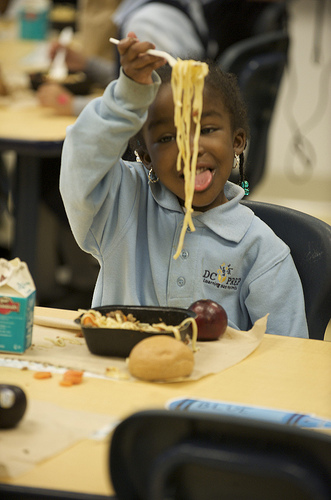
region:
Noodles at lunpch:
[153, 44, 232, 228]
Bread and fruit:
[101, 278, 238, 372]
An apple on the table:
[180, 288, 224, 338]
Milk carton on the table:
[15, 253, 34, 345]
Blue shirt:
[95, 127, 243, 236]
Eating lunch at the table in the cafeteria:
[6, 29, 294, 438]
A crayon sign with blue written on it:
[154, 371, 329, 451]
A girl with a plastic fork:
[83, 18, 254, 112]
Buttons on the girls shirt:
[160, 201, 225, 321]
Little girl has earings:
[145, 150, 271, 262]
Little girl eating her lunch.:
[51, 31, 309, 321]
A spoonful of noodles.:
[149, 38, 222, 282]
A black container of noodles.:
[73, 297, 215, 358]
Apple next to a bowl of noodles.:
[179, 291, 233, 346]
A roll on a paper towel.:
[124, 331, 200, 386]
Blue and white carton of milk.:
[0, 248, 43, 358]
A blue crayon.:
[159, 387, 330, 445]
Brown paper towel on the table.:
[39, 309, 289, 385]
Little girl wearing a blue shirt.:
[43, 38, 313, 339]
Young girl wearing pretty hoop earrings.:
[72, 33, 278, 223]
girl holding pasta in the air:
[140, 39, 203, 270]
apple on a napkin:
[184, 298, 229, 352]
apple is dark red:
[191, 299, 229, 341]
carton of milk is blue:
[0, 266, 36, 359]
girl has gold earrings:
[136, 151, 243, 183]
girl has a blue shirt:
[90, 157, 315, 334]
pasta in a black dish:
[72, 297, 200, 348]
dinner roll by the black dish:
[85, 326, 200, 378]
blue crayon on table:
[169, 387, 328, 433]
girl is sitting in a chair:
[227, 192, 329, 324]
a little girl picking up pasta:
[107, 32, 243, 259]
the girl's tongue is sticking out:
[133, 58, 246, 227]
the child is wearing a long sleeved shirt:
[58, 69, 307, 338]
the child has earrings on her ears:
[140, 145, 240, 182]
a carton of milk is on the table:
[1, 252, 34, 354]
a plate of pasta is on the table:
[71, 300, 194, 355]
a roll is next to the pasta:
[125, 333, 192, 378]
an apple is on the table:
[184, 297, 226, 340]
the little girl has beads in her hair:
[236, 172, 251, 197]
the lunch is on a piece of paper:
[1, 258, 268, 382]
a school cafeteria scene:
[10, 8, 303, 447]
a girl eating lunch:
[8, 41, 299, 491]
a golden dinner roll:
[121, 327, 208, 388]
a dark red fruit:
[181, 296, 234, 342]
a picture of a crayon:
[159, 383, 329, 442]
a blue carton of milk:
[0, 255, 53, 358]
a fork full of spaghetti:
[102, 34, 214, 259]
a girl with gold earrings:
[106, 36, 261, 214]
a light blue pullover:
[59, 64, 310, 335]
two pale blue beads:
[237, 173, 253, 199]